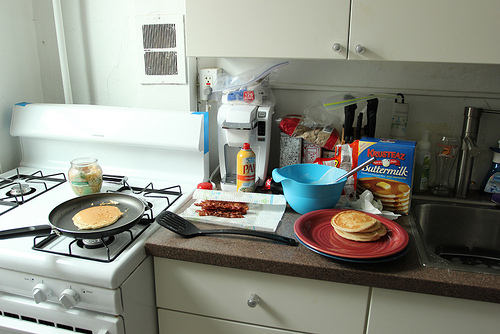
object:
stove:
[3, 103, 202, 332]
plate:
[293, 207, 411, 259]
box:
[352, 139, 416, 217]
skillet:
[0, 191, 146, 251]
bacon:
[193, 195, 250, 218]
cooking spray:
[236, 144, 256, 193]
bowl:
[272, 163, 347, 217]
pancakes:
[71, 204, 122, 231]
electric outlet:
[198, 69, 217, 97]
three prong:
[196, 80, 217, 101]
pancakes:
[330, 208, 389, 242]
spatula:
[156, 210, 299, 239]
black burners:
[0, 172, 189, 262]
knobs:
[54, 285, 81, 310]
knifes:
[364, 96, 380, 140]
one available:
[196, 72, 215, 83]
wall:
[49, 1, 193, 114]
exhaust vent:
[136, 13, 187, 88]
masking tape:
[190, 111, 208, 153]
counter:
[150, 179, 499, 330]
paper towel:
[171, 188, 289, 230]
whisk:
[337, 154, 378, 186]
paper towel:
[389, 93, 409, 143]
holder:
[392, 89, 412, 145]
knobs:
[348, 41, 368, 58]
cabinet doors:
[182, 1, 499, 64]